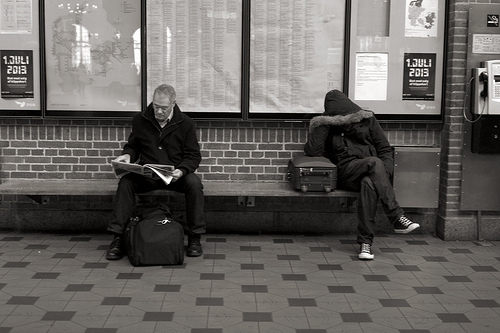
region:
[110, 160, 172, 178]
newspaper in black and white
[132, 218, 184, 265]
a black bag with a silver zipper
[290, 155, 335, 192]
black suitcase with zipper and wheels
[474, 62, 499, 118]
pay telephone not currently in use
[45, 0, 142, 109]
a terminal map behind a layer of plexiglass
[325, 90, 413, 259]
a sleeping passenger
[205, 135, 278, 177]
a brick wall in black and white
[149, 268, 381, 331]
hexagonal pattern of floor tiles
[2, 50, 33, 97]
poster with light colored text in black and white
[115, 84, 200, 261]
an older gentleman reading the paper with a bag at his feet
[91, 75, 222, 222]
a man reading a newspaper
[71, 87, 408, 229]
two people sitting on a bench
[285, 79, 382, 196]
a person with their head covered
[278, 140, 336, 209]
a suitcase on a bench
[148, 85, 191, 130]
a man wearing glasses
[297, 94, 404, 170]
a person with the hood of a jacket on their head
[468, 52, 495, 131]
a pay telephone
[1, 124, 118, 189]
a brick wall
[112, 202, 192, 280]
a suitcase on the floor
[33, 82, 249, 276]
a man sitting on a bench reading a paper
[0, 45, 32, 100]
small paper in the wall in the left side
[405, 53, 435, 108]
small paper in the right side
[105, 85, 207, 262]
man sitting in a bench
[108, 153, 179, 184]
man reading a newspaper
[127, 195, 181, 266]
black bag in floor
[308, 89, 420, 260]
woman sitting in a bench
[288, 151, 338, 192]
big bag above bench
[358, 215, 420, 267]
black and white converse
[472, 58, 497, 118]
public phone hanging in the wall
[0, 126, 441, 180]
part of brick wall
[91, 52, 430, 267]
2 people sitting on a bench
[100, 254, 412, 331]
the floor is 2 colors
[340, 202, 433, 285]
person is wearing sneakers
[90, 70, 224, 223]
man is reading the newspaper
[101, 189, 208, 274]
bag sitting under the bench between the man`s feet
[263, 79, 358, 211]
person leaning on the bag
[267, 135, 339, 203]
suit case on the bench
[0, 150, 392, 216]
the bench is long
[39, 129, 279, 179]
the wall is made of bricks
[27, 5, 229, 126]
the window is reflecting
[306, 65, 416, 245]
This person's face is covered.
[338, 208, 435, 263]
The person is wearing Converse shoes.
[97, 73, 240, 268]
This man has on a peacoat.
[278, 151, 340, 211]
This is a suit case.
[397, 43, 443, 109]
This says "1 Juli 2013"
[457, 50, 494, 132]
This is a telephone.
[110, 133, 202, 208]
This is a newspaper.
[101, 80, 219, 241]
The man is reading a newspaper.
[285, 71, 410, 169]
This man has fur on his hood.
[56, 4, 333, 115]
This glass display has paper inside it.